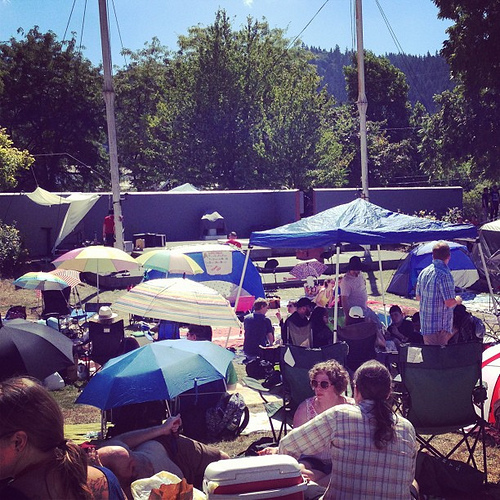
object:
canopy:
[247, 195, 478, 252]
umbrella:
[71, 338, 238, 440]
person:
[90, 412, 234, 498]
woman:
[291, 358, 359, 433]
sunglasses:
[311, 379, 334, 390]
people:
[304, 304, 340, 351]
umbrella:
[0, 317, 77, 385]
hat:
[93, 305, 119, 320]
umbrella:
[50, 243, 141, 315]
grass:
[0, 275, 500, 500]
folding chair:
[87, 319, 140, 382]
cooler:
[200, 452, 311, 500]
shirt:
[274, 403, 420, 499]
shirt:
[416, 259, 457, 337]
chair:
[395, 340, 491, 498]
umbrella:
[132, 246, 205, 279]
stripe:
[98, 313, 112, 319]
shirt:
[310, 288, 332, 309]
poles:
[332, 245, 341, 347]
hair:
[307, 358, 350, 396]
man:
[277, 358, 420, 500]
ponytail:
[367, 397, 401, 451]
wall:
[0, 186, 464, 260]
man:
[416, 240, 463, 349]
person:
[283, 297, 316, 346]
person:
[336, 306, 387, 350]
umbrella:
[107, 276, 242, 340]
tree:
[247, 73, 357, 219]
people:
[101, 207, 119, 247]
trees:
[338, 48, 417, 190]